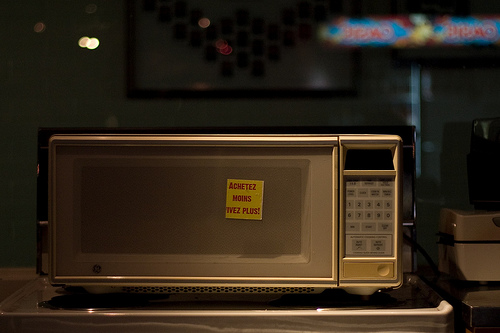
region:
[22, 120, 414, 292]
microwave sitting on countertop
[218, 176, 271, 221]
yellow sticker with red lettering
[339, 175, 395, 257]
control panel of the microwave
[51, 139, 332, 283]
door of the microwave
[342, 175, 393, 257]
gray buttons with black lettering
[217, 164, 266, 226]
sticker on the microwave door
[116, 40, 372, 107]
picture frame hanging on wall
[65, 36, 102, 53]
reflection of light on back wall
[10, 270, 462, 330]
countertop microwave is sitting on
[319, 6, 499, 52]
blue and red reflection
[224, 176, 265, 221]
yellow sign with red print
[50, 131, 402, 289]
beige microwave with yellow sign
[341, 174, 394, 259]
keypad of unplugged microwave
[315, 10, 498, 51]
blue red and yellow sign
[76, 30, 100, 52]
yellow lights out of focus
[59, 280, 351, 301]
ventilated underside of microwave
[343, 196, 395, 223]
surface numbered 1 through 9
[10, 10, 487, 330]
darkened room with microwave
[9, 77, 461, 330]
microwave on a table in a darkened room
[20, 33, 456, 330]
old unpowered microwave in a dark place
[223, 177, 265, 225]
sticker on front of microwave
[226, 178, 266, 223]
The sticker is yellow and red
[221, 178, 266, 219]
the lettering is in red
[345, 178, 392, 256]
buttons on the side of the microwave used to set time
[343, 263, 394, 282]
button used to open the microwave door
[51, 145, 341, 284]
microwave door its color is beige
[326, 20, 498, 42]
out of focus item is back ground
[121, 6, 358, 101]
picture on the wall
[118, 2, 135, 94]
the frame of the picture is black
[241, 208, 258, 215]
the word is plus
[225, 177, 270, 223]
red and white sign on the microwave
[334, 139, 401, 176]
black screen on the microwave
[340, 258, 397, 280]
white opening button on the microwave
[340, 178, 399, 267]
white and gray buttons on the side of the microwave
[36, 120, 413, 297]
a microwave sitting on the counter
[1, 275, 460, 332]
a counter under the microwave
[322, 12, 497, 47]
a blue and red sign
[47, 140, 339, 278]
door of the microwave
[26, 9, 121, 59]
lights reflecting off of the wall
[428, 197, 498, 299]
small toaster next to the microwave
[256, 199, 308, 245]
part of a front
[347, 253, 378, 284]
part of a switch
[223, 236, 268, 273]
part of a microwave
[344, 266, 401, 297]
part of an edge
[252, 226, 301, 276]
aprt of a screen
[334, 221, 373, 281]
part of a sticker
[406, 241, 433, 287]
paert of a pipe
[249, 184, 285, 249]
part of a glass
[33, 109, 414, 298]
The white microwave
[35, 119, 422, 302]
A white microwave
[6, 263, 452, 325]
The silver tray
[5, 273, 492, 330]
A silver tray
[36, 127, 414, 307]
A white microwave oven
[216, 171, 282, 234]
The red and white sticker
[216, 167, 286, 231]
A red and white sticker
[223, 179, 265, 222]
Yellow sticker with red writing.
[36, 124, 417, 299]
Mostly white microwave.